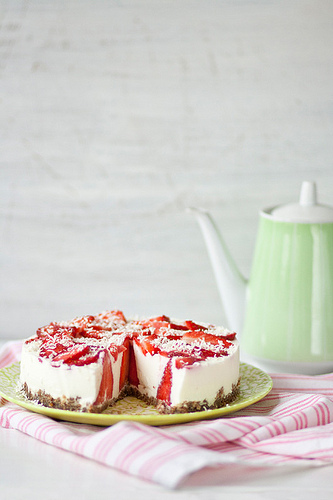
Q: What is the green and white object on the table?
A: A coffee pot.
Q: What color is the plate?
A: Green.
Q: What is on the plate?
A: Dessert.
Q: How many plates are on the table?
A: One.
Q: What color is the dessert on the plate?
A: Red and white.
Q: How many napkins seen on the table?
A: One.